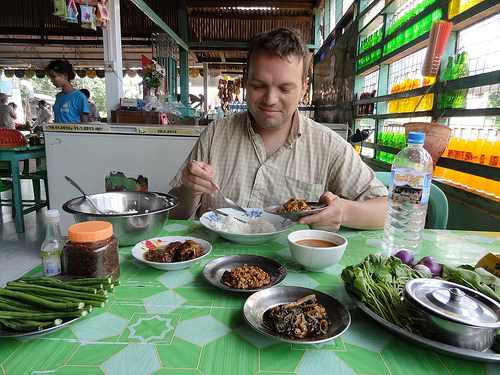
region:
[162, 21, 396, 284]
a man in front a table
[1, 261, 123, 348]
a dish with green beans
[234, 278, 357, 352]
a silver bowl with meat sauce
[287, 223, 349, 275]
a bowl of soup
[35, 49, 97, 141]
person wearing a blue top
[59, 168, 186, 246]
a silver bowl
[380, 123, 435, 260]
a bottle of water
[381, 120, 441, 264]
bottle of water with blue cap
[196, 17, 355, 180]
a happy smiling man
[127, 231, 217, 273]
a white dish with meat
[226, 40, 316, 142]
face of the person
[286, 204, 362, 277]
a cup with coffee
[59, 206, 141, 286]
a small bottle in table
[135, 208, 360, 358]
a group of food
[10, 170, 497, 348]
a large table with food items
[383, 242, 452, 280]
onions in the plate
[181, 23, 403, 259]
a man going to eat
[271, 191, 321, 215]
a plate holding by person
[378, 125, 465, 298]
a water bottle placed in table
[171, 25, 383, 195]
A man wearing a plaid shirt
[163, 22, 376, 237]
A man eating white rice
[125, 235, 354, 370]
Food sitting on a green table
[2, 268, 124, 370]
Fresh cut green beans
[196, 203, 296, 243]
White rice in a white & blue bowl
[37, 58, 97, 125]
A woman wearing a blue shirt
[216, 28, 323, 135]
A white man smiling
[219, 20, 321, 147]
A man with dark brown hair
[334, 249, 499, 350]
Green leafy vegetables on a platter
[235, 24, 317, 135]
A man closing his eyes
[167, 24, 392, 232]
man dining in restaurant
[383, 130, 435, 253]
bottle of drinking water on table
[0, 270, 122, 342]
serving plate full of green vegetables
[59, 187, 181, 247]
metal bowl of white rice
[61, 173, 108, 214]
serving spoon in bowl of rice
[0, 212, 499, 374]
dining table covered with green tablecloth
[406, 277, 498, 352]
metal serving dish with lid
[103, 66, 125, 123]
white support beam for building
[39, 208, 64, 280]
partially empty sauce bottle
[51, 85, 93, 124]
a blue shirt on a woman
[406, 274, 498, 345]
a metal dish with a lid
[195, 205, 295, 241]
a bowl of rice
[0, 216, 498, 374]
a green and white table top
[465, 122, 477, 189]
an orange drink in a glass bottle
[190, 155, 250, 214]
a spoon in a man's hand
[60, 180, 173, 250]
a large metal serving bowl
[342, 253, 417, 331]
greens on a metal plate